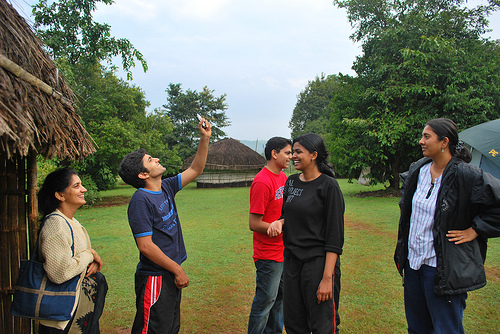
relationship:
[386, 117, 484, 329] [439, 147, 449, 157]
woman wearing earring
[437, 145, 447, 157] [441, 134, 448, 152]
earring on ear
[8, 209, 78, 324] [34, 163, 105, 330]
bag on lady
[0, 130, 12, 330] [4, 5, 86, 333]
pole on hut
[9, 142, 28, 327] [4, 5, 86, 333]
pole on hut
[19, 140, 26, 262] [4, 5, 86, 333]
pole on hut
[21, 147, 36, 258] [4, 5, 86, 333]
pole on hut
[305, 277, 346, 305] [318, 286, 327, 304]
ring on finger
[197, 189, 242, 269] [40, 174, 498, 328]
grass on ground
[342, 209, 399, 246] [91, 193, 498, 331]
path on ground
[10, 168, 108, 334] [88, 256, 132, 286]
lady wearing ring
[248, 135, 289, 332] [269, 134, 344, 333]
guy standing with woman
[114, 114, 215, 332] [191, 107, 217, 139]
guy holding cellphone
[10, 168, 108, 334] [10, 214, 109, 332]
lady carrying bag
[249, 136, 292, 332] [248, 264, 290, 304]
guy wearing jeans